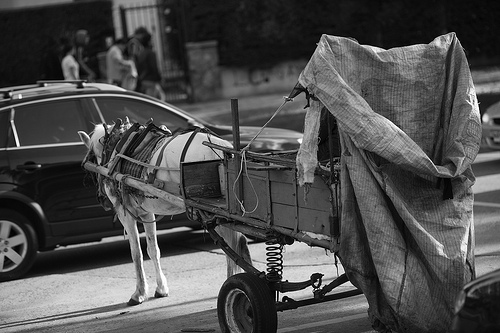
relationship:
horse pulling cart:
[65, 103, 249, 258] [217, 80, 444, 281]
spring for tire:
[256, 207, 293, 282] [215, 271, 279, 333]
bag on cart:
[317, 64, 492, 284] [217, 80, 444, 281]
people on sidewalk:
[59, 24, 154, 89] [206, 83, 497, 129]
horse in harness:
[65, 103, 249, 258] [104, 134, 169, 175]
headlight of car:
[477, 101, 498, 140] [16, 77, 319, 255]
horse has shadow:
[65, 103, 249, 258] [22, 292, 144, 332]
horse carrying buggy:
[65, 103, 249, 258] [217, 80, 444, 281]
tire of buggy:
[215, 271, 279, 333] [217, 80, 444, 281]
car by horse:
[16, 77, 319, 255] [65, 103, 249, 258]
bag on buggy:
[317, 64, 492, 284] [235, 122, 424, 258]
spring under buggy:
[261, 223, 282, 282] [235, 122, 424, 258]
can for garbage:
[175, 28, 236, 123] [185, 40, 217, 48]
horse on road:
[65, 103, 249, 258] [0, 71, 497, 333]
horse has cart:
[65, 103, 249, 258] [217, 80, 444, 281]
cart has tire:
[217, 80, 444, 281] [215, 271, 279, 333]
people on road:
[59, 24, 154, 89] [150, 68, 299, 124]